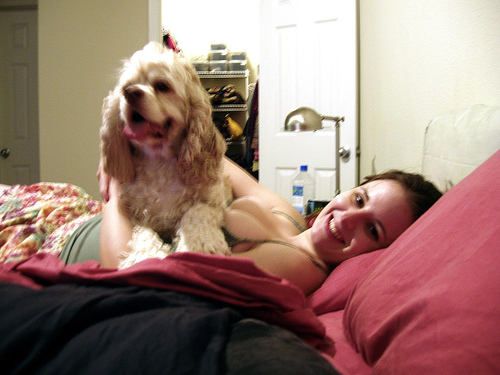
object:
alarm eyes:
[351, 190, 367, 211]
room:
[0, 0, 498, 374]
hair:
[304, 170, 442, 227]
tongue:
[120, 118, 152, 140]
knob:
[335, 146, 350, 165]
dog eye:
[152, 78, 176, 93]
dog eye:
[122, 82, 129, 88]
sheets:
[0, 250, 340, 357]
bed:
[0, 105, 499, 374]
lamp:
[281, 105, 323, 133]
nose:
[337, 209, 360, 230]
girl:
[0, 153, 444, 298]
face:
[317, 180, 411, 261]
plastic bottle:
[290, 166, 315, 215]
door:
[257, 0, 358, 230]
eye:
[365, 220, 382, 242]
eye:
[350, 190, 364, 211]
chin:
[310, 219, 338, 263]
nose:
[120, 81, 144, 103]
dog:
[97, 41, 232, 272]